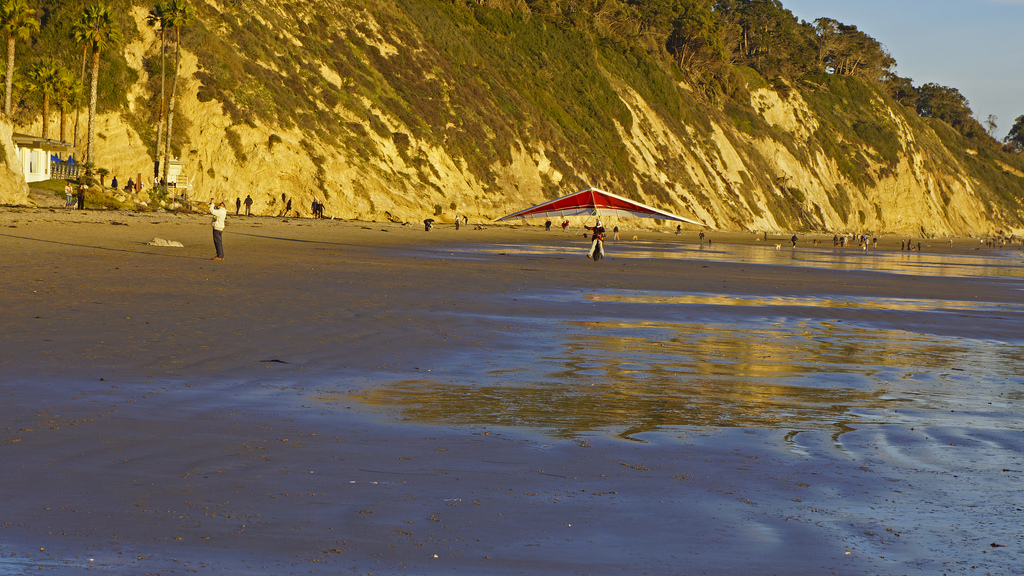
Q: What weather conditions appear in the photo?
A: It is clear.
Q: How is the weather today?
A: It is clear.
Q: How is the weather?
A: It is clear.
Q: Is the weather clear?
A: Yes, it is clear.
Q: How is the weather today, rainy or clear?
A: It is clear.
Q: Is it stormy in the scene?
A: No, it is clear.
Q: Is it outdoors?
A: Yes, it is outdoors.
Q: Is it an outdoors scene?
A: Yes, it is outdoors.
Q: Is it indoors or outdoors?
A: It is outdoors.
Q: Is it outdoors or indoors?
A: It is outdoors.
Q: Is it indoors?
A: No, it is outdoors.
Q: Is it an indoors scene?
A: No, it is outdoors.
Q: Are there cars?
A: No, there are no cars.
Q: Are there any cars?
A: No, there are no cars.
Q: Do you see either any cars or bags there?
A: No, there are no cars or bags.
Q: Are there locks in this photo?
A: No, there are no locks.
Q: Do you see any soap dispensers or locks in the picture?
A: No, there are no locks or soap dispensers.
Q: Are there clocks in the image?
A: No, there are no clocks.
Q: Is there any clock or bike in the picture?
A: No, there are no clocks or bikes.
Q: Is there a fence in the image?
A: No, there are no fences.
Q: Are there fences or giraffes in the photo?
A: No, there are no fences or giraffes.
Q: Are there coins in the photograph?
A: No, there are no coins.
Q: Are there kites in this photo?
A: Yes, there is a kite.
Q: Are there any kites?
A: Yes, there is a kite.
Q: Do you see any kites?
A: Yes, there is a kite.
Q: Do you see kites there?
A: Yes, there is a kite.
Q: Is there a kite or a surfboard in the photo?
A: Yes, there is a kite.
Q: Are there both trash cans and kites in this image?
A: No, there is a kite but no trash cans.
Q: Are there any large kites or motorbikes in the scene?
A: Yes, there is a large kite.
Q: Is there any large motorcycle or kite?
A: Yes, there is a large kite.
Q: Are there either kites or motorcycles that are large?
A: Yes, the kite is large.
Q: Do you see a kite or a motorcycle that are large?
A: Yes, the kite is large.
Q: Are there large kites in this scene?
A: Yes, there is a large kite.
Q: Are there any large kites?
A: Yes, there is a large kite.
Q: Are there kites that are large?
A: Yes, there is a kite that is large.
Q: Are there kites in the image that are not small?
A: Yes, there is a large kite.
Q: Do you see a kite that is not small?
A: Yes, there is a large kite.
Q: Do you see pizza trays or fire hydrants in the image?
A: No, there are no pizza trays or fire hydrants.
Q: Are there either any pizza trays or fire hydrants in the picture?
A: No, there are no pizza trays or fire hydrants.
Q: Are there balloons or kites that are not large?
A: No, there is a kite but it is large.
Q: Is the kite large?
A: Yes, the kite is large.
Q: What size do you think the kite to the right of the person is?
A: The kite is large.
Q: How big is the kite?
A: The kite is large.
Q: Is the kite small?
A: No, the kite is large.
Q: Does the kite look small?
A: No, the kite is large.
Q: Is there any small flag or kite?
A: No, there is a kite but it is large.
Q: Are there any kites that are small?
A: No, there is a kite but it is large.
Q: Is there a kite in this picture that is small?
A: No, there is a kite but it is large.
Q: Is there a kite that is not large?
A: No, there is a kite but it is large.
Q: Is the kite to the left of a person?
A: No, the kite is to the right of a person.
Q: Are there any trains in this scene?
A: No, there are no trains.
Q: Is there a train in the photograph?
A: No, there are no trains.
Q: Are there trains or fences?
A: No, there are no trains or fences.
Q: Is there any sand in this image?
A: Yes, there is sand.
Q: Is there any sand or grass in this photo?
A: Yes, there is sand.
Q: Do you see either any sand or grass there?
A: Yes, there is sand.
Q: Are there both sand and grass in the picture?
A: Yes, there are both sand and grass.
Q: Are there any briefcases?
A: No, there are no briefcases.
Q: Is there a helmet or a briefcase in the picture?
A: No, there are no briefcases or helmets.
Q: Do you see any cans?
A: No, there are no cans.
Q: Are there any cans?
A: No, there are no cans.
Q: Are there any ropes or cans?
A: No, there are no cans or ropes.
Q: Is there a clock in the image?
A: No, there are no clocks.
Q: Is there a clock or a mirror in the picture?
A: No, there are no clocks or mirrors.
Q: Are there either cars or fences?
A: No, there are no cars or fences.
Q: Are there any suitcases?
A: No, there are no suitcases.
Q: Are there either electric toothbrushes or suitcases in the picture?
A: No, there are no suitcases or electric toothbrushes.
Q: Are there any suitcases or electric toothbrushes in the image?
A: No, there are no suitcases or electric toothbrushes.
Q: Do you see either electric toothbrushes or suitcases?
A: No, there are no suitcases or electric toothbrushes.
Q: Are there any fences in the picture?
A: No, there are no fences.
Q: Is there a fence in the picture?
A: No, there are no fences.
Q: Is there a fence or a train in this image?
A: No, there are no fences or trains.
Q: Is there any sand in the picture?
A: Yes, there is sand.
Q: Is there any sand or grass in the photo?
A: Yes, there is sand.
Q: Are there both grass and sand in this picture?
A: Yes, there are both sand and grass.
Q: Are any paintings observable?
A: No, there are no paintings.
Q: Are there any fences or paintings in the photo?
A: No, there are no paintings or fences.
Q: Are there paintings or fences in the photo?
A: No, there are no paintings or fences.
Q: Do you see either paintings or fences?
A: No, there are no paintings or fences.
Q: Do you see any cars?
A: No, there are no cars.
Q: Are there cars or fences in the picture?
A: No, there are no cars or fences.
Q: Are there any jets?
A: No, there are no jets.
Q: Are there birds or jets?
A: No, there are no jets or birds.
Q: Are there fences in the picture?
A: No, there are no fences.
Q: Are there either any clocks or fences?
A: No, there are no fences or clocks.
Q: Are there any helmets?
A: No, there are no helmets.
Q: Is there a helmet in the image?
A: No, there are no helmets.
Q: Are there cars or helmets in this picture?
A: No, there are no helmets or cars.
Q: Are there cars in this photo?
A: No, there are no cars.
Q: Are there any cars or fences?
A: No, there are no cars or fences.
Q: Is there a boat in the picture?
A: No, there are no boats.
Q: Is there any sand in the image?
A: Yes, there is sand.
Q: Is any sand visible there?
A: Yes, there is sand.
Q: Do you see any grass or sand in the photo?
A: Yes, there is sand.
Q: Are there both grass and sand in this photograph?
A: Yes, there are both sand and grass.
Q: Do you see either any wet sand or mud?
A: Yes, there is wet sand.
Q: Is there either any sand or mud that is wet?
A: Yes, the sand is wet.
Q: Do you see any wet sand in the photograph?
A: Yes, there is wet sand.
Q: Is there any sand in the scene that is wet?
A: Yes, there is sand that is wet.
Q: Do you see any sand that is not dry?
A: Yes, there is wet sand.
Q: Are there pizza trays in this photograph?
A: No, there are no pizza trays.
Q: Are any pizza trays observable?
A: No, there are no pizza trays.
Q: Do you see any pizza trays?
A: No, there are no pizza trays.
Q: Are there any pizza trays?
A: No, there are no pizza trays.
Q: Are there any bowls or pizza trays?
A: No, there are no pizza trays or bowls.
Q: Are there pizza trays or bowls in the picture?
A: No, there are no pizza trays or bowls.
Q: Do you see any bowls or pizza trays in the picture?
A: No, there are no pizza trays or bowls.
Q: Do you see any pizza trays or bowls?
A: No, there are no pizza trays or bowls.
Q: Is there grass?
A: Yes, there is grass.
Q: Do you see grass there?
A: Yes, there is grass.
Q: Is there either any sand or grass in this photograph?
A: Yes, there is grass.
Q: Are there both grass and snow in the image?
A: No, there is grass but no snow.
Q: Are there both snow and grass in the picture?
A: No, there is grass but no snow.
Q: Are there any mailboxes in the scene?
A: No, there are no mailboxes.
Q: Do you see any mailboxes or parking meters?
A: No, there are no mailboxes or parking meters.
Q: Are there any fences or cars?
A: No, there are no cars or fences.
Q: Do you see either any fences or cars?
A: No, there are no cars or fences.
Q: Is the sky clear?
A: Yes, the sky is clear.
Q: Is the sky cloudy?
A: No, the sky is clear.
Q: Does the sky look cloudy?
A: No, the sky is clear.